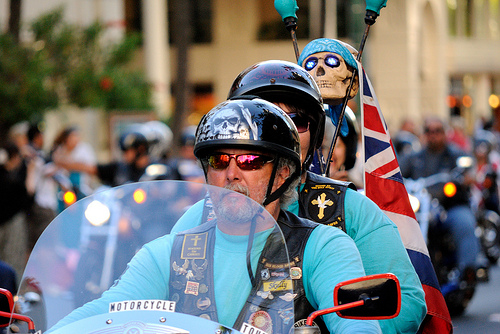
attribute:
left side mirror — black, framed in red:
[308, 272, 402, 321]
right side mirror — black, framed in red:
[0, 287, 35, 333]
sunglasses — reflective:
[202, 151, 276, 171]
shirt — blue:
[40, 224, 380, 333]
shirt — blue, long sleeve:
[172, 174, 428, 333]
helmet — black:
[192, 99, 303, 224]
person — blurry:
[399, 120, 490, 285]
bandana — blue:
[298, 37, 358, 70]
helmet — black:
[227, 60, 326, 150]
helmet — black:
[325, 105, 360, 169]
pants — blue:
[444, 206, 478, 272]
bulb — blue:
[366, 1, 388, 22]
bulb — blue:
[273, 2, 300, 31]